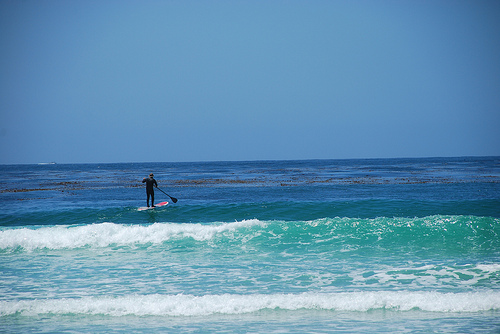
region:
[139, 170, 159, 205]
A man standing on a board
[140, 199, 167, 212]
A red and white board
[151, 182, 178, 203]
A black paddle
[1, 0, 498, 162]
A clear blue sky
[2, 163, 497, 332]
The ocean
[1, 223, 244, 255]
A wave crashing down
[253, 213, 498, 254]
A wave beginning to crest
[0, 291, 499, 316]
A small wave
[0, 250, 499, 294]
Some sea foam in the water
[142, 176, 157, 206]
A black wet suit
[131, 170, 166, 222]
man standing on paddleboard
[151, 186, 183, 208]
paddle being used by man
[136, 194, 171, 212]
board floating on water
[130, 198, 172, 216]
white paddleboard man is standing on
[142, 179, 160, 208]
black wetsuit of man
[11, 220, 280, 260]
white foam of wave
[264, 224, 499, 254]
swell of the ave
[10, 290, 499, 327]
water lapping onto shore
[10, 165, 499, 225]
waters paddleboard is riding on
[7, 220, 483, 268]
wave crashing back into ocean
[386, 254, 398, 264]
part of the sea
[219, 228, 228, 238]
part of the ocean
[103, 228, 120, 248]
part of a wave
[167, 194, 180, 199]
part of a paddle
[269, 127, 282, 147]
part of the sky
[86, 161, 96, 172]
part of the ocean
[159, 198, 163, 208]
part of a board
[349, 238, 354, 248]
tip of a wave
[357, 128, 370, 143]
part of the sky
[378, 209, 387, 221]
edge of a wave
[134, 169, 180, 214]
wan surf boarding in the water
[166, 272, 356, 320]
small wave coming forward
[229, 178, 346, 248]
ripple of waves on the ocean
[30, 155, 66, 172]
boat in the distance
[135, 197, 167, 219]
red and white surf board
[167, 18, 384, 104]
clear blue bright sky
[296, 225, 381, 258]
aqua colored blue water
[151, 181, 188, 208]
person holding black pedal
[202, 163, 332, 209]
calm blue ocean waters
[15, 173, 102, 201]
material on top of water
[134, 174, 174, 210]
the person is on a board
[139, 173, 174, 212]
the person is holding a paddle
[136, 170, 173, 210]
the person is dressed in black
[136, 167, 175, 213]
the person is paddle boarding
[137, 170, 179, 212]
the board is red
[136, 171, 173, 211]
the person is in the ocean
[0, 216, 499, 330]
the wave is crashing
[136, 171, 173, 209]
the person stands on a paddle board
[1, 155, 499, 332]
the water is blue and green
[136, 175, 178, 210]
the person is alone